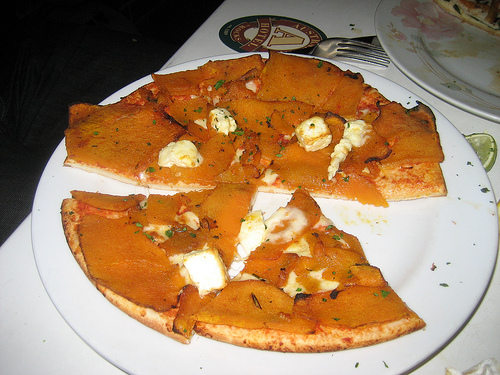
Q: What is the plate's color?
A: White.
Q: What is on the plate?
A: Pizza.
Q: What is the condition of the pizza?
A: Cooked.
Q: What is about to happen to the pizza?
A: Eaten.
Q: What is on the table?
A: Pizza.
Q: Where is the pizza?
A: On the plate.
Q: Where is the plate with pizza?
A: On the table.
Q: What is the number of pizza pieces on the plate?
A: 3.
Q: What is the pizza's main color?
A: Orange.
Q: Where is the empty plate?
A: Behind the pizza.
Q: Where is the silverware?
A: Behind the pizza.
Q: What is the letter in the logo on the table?
A: A.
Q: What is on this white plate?
A: Slice of pizza.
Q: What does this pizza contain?
A: Orange topping.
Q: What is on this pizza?
A: Goat cheese.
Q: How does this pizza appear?
A: Triangular.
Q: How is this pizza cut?
A: Into triangles.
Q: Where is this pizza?
A: On white plate.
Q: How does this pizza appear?
A: Two slices.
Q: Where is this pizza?
A: On white plate.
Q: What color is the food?
A: Brown.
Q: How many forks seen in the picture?
A: One.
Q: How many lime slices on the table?
A: One.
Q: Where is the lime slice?
A: Under the plate.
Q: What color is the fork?
A: Silver.